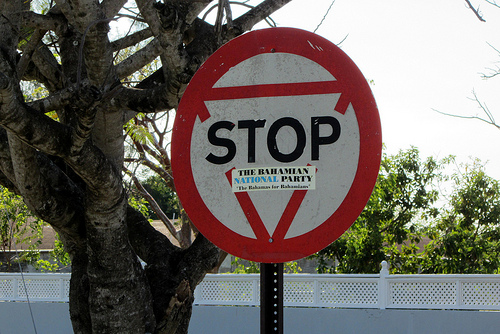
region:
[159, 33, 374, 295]
a sign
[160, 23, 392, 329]
a red circle stop sign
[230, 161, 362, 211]
a political sticker on the stop sign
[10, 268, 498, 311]
the fence is white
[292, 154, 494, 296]
trees behind the fence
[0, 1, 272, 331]
a brown tree trunk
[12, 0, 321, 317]
the tree trunk is twisted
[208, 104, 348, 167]
the letters are black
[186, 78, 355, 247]
the triangle is red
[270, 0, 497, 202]
the sky is grey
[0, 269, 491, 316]
the fence has holes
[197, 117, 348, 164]
black writing on sign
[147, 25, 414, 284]
black and red stop sign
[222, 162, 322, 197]
sticker on middle of stop sign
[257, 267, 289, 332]
black metal sign post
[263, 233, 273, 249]
silver bolt securing stop sign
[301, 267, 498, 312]
white wooden fencing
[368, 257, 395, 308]
white wooden fence post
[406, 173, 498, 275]
tree with green leaves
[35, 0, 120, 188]
tree limbs with no leaves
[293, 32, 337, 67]
white scratch on sign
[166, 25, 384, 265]
a red and white stop sign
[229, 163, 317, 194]
a sticker on stop sign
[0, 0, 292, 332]
a twisted branched tree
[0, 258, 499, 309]
a long white fence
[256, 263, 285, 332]
metal post signs attached to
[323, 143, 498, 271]
leafy green trees behind fence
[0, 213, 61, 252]
part of roof of house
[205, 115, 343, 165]
black lettering says STOP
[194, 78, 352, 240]
triangle shape on sign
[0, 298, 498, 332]
grey section of road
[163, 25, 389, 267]
The sign is round.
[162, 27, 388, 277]
Sign has bumper sticker on it.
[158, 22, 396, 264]
Black letters on sign.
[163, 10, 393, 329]
Sign is on a pole.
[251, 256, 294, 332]
The pole is metal.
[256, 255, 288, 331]
The pole is straight.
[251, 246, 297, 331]
Pole has holes in it.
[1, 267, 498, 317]
Long fence in background.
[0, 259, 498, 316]
The fence is white.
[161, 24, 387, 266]
Sign is red, white and black.